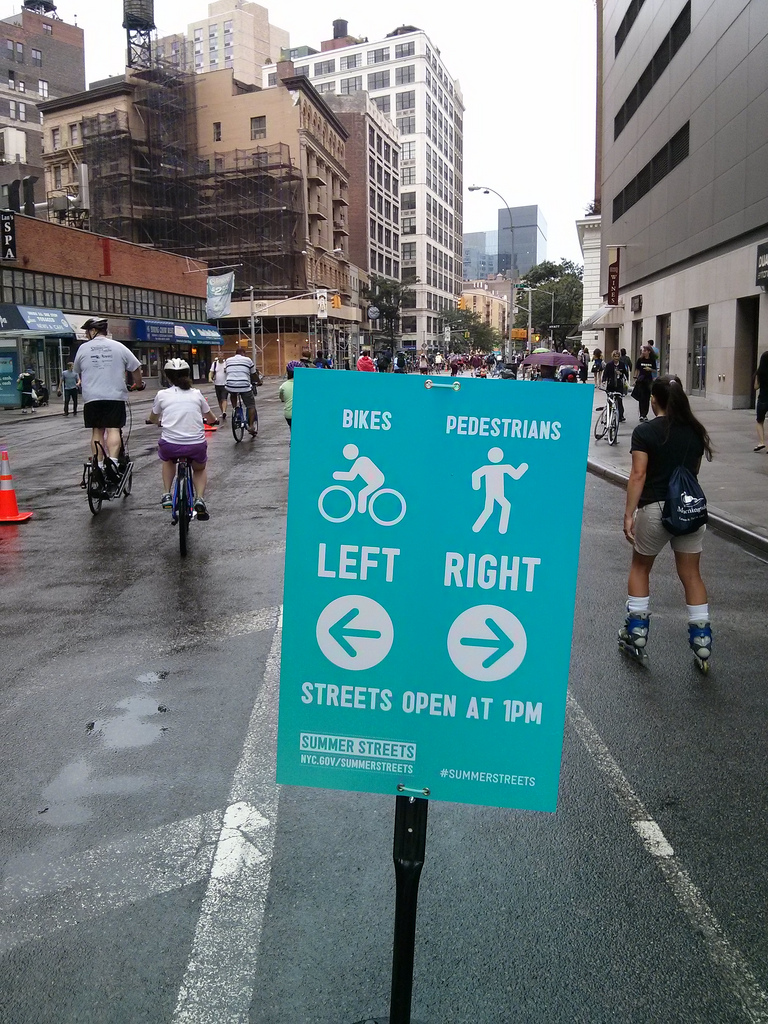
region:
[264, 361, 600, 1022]
aqua and white sign on street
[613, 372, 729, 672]
woman is wearing rollerblades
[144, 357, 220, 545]
woman riding a bike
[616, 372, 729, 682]
woman carrying a bag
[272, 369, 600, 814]
picture of bike on sign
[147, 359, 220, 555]
woman wearing a helmet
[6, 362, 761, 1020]
white line on street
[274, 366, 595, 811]
a sign for directing foot and bicycle traffic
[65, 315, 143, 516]
a man riding a stand-up cycle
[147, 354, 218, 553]
a girl on a bicycle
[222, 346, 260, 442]
a man on a bicycle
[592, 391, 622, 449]
a parked bicycle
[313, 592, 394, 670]
an arrow pointing left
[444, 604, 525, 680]
an arrow pointing right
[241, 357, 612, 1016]
a sign is color turquoise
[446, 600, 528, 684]
an arrow to the right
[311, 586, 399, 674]
an arrow to the left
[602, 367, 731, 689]
the man has long hair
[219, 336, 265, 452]
the man is riding a bike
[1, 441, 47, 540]
the cone is white and orange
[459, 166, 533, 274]
the light is silver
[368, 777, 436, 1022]
the black is color black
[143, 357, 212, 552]
A person is riding a bike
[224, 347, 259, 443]
A person is riding a bike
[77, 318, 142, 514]
A person is riding a bike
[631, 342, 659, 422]
A woman is walking on the sidewalk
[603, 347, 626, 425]
A woman is walking on the sidewalk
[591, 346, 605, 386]
A woman is walking on the sidewalk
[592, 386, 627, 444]
A bike is on the sidewalk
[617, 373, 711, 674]
Woman is rollerblading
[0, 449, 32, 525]
Orange and white cane on the street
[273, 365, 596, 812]
Blue and white street sign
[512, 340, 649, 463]
corner of the sign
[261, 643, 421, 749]
white word on blue sign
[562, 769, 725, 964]
white line on ground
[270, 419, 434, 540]
picture of a being on a bike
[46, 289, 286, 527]
people riding on bikes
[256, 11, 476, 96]
top of the building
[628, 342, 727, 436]
head of the girl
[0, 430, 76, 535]
cone on the ground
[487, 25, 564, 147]
sky above the land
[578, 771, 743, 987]
line on the street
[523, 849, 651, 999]
black street under sign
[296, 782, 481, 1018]
black pole under sign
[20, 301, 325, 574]
people riding on bikes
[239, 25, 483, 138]
top of a building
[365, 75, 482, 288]
many windows on the building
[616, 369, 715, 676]
a woman on roller blades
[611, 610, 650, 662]
a blue roller blade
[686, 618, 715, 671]
a blue roller blade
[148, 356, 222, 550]
a woman riding a bicycle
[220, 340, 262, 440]
a man riding a bicycle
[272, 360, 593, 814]
a street informational sign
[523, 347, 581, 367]
an open purple umbrella